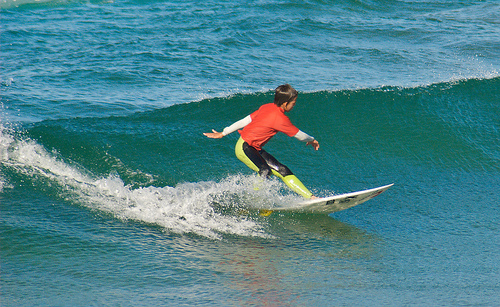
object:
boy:
[202, 84, 320, 202]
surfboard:
[255, 182, 398, 212]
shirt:
[237, 102, 298, 151]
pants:
[235, 135, 314, 206]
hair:
[273, 84, 298, 109]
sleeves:
[222, 115, 314, 144]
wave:
[1, 73, 498, 236]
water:
[5, 3, 491, 306]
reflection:
[209, 210, 380, 304]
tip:
[358, 181, 397, 200]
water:
[1, 122, 300, 249]